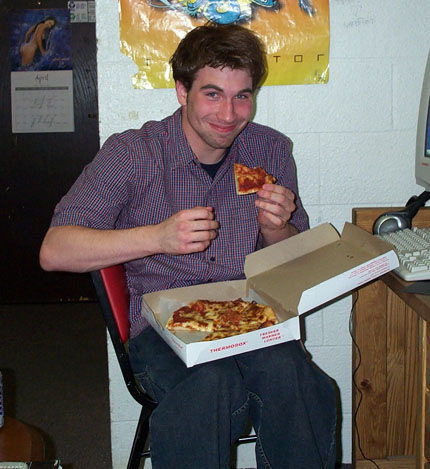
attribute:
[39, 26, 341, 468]
man — smiling, white